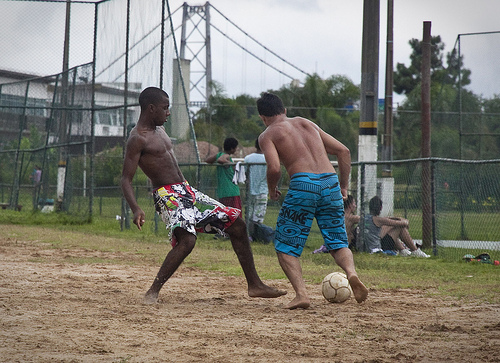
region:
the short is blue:
[280, 169, 355, 259]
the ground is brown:
[38, 271, 125, 342]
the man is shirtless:
[121, 126, 247, 286]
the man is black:
[122, 105, 263, 301]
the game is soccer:
[0, 97, 482, 350]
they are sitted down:
[350, 195, 421, 255]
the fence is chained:
[400, 140, 496, 231]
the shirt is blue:
[212, 152, 240, 193]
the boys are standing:
[208, 135, 264, 206]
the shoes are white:
[405, 245, 432, 265]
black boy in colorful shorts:
[118, 87, 283, 299]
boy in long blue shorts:
[257, 90, 375, 310]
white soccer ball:
[319, 271, 354, 301]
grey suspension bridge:
[81, 0, 322, 112]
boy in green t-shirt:
[207, 134, 244, 211]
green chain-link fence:
[0, 66, 117, 224]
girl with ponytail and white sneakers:
[361, 194, 429, 259]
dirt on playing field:
[1, 281, 499, 362]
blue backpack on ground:
[246, 218, 273, 246]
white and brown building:
[0, 68, 141, 146]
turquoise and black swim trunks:
[270, 167, 354, 254]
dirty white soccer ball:
[318, 270, 354, 302]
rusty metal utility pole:
[417, 43, 437, 251]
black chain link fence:
[7, 76, 93, 216]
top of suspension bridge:
[89, 0, 332, 122]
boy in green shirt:
[202, 137, 247, 196]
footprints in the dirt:
[93, 272, 350, 361]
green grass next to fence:
[357, 246, 488, 281]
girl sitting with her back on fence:
[355, 195, 428, 259]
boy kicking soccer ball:
[255, 78, 374, 315]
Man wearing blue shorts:
[253, 83, 373, 306]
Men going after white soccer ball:
[117, 80, 372, 311]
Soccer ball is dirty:
[316, 265, 352, 297]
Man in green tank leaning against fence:
[200, 132, 241, 213]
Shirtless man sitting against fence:
[340, 190, 355, 240]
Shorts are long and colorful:
[150, 177, 251, 242]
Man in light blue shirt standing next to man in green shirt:
[240, 137, 270, 222]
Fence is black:
[0, 155, 495, 265]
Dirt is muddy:
[1, 240, 496, 357]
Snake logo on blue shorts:
[278, 201, 313, 224]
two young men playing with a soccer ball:
[99, 65, 401, 315]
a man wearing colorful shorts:
[92, 77, 236, 264]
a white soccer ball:
[306, 266, 376, 309]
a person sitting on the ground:
[357, 181, 421, 256]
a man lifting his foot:
[79, 83, 271, 324]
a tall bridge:
[102, 8, 245, 104]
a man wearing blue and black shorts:
[255, 65, 360, 301]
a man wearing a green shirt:
[208, 126, 238, 206]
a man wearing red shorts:
[205, 137, 245, 208]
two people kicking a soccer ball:
[41, 78, 391, 325]